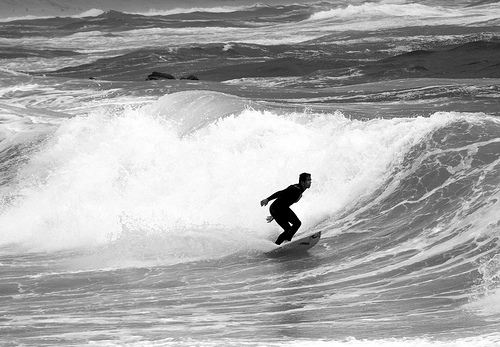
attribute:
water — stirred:
[72, 109, 235, 223]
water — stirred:
[315, 113, 404, 203]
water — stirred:
[1, 182, 97, 252]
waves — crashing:
[12, 53, 484, 274]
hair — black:
[295, 169, 313, 189]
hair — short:
[293, 167, 314, 190]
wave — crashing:
[6, 82, 466, 271]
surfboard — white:
[264, 229, 324, 257]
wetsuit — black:
[266, 183, 304, 240]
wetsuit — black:
[274, 180, 306, 237]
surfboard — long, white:
[260, 231, 320, 253]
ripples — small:
[145, 21, 455, 111]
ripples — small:
[7, 73, 112, 155]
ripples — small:
[7, 16, 115, 93]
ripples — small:
[266, 19, 491, 85]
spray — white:
[32, 100, 413, 251]